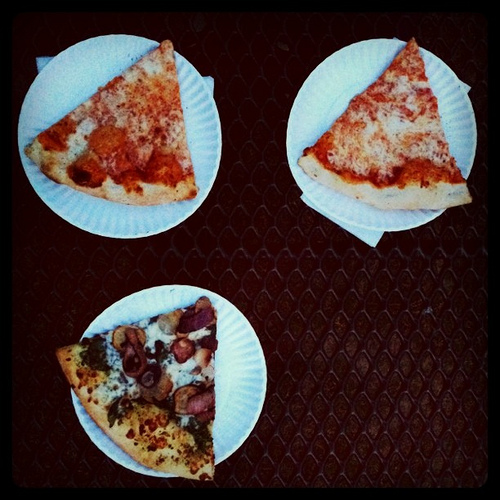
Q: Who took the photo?
A: A photographer.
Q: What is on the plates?
A: Pizza.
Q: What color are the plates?
A: White.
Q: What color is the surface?
A: Brown.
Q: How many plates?
A: Three.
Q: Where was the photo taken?
A: In the pizza shop.